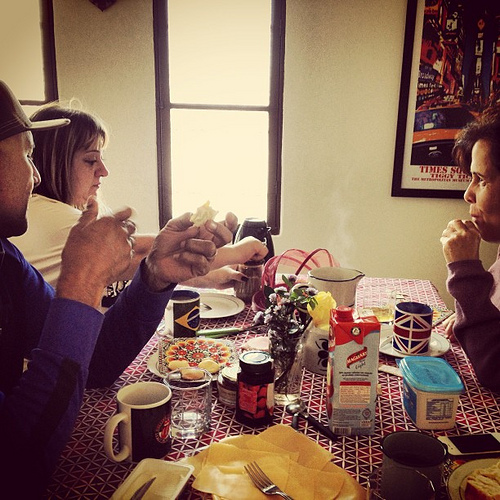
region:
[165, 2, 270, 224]
a window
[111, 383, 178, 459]
a mug on the table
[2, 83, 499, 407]
people sitting around a table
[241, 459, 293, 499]
a fork on the table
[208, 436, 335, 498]
napkins on a plate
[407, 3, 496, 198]
a picture on the wall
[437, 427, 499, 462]
a phone on the table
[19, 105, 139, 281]
a woman in a white shirt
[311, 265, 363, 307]
a pitcher on the table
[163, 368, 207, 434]
a glass on the table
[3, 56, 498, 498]
people sitting around table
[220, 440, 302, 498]
silver fork on table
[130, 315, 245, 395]
plate of cookies on table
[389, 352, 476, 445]
carton of butter on table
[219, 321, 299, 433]
jar of jelly on table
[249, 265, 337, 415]
vase of flowers on table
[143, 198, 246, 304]
man holding piece of bread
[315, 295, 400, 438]
carton of milk on table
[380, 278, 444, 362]
british mug on plate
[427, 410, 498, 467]
cell phone on table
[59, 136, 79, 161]
Person has brown hair.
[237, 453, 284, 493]
Silver fork sitting on cheese.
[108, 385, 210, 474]
Coffee mug sitting on table.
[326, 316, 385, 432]
Red and gray carton sitting on table.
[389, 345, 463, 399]
Blue lid on top of container.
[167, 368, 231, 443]
Clear glass sitting on table.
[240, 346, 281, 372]
Black lid on top of container.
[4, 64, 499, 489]
people sitting around table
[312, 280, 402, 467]
carton of milk on table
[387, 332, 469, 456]
carton of butter on table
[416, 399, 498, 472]
cell phone on table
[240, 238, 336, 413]
vase of flowers on table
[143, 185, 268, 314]
lady opening up jar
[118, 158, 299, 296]
man holding piece of bread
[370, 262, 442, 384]
british colored mug on plate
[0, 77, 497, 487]
Three people eating at a table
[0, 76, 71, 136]
Front end of a baseball cap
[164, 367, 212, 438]
Drinking glass on a table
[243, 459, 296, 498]
Tine end of a silver fork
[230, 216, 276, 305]
Black coffee server on a table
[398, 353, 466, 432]
Container of butter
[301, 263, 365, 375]
Ceramic water pitcher on a table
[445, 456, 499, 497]
A piece of bread on a plate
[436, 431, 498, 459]
White smartphone on a table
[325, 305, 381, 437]
Container of coffee creamer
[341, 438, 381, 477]
a pattern with lots of white triangles on red background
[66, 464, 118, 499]
a pattern with lots of white triangles on red background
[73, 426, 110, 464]
a pattern with lots of white triangles on red background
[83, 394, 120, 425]
a pattern with lots of white triangles on red background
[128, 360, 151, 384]
a pattern with lots of white triangles on red background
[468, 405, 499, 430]
a pattern with lots of white triangles on red background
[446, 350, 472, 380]
a pattern with lots of white triangles on red background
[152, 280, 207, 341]
cup with Brazil flag on it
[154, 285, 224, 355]
cup with Brazil flag on it